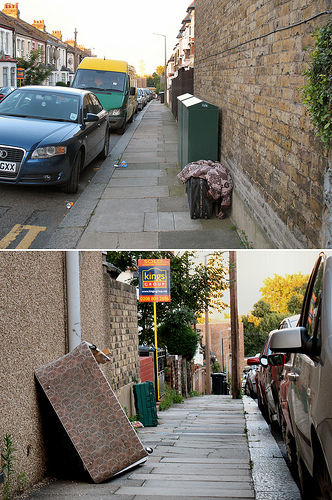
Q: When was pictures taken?
A: Daytime.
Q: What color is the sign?
A: Orange, black, blue, and yellow.